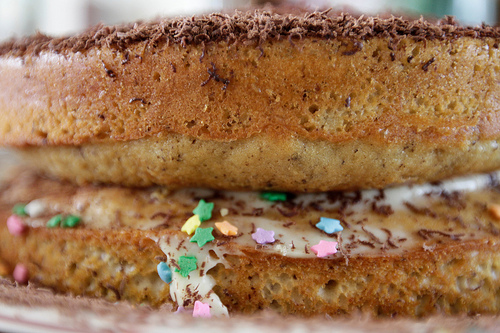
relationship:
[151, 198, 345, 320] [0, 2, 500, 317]
sprinkles on pancake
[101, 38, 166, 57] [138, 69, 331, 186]
shavings on pancake